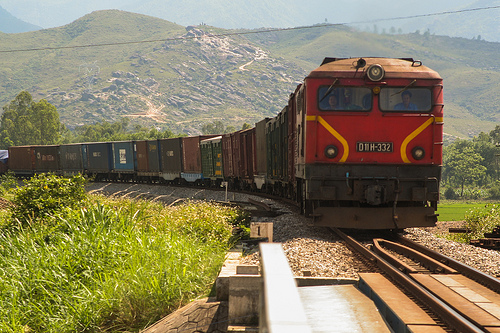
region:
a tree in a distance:
[34, 165, 83, 213]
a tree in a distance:
[1, 88, 63, 151]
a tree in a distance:
[34, 97, 65, 142]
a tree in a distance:
[73, 120, 103, 139]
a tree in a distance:
[108, 118, 130, 140]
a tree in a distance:
[141, 124, 171, 138]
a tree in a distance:
[439, 138, 483, 187]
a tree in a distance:
[470, 130, 497, 153]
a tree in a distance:
[389, 23, 398, 35]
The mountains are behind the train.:
[13, 4, 400, 96]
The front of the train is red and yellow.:
[285, 43, 446, 241]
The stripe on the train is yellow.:
[393, 114, 448, 166]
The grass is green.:
[8, 163, 195, 283]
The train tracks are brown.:
[342, 212, 485, 296]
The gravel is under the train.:
[271, 202, 388, 284]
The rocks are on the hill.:
[122, 0, 278, 132]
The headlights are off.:
[296, 132, 452, 174]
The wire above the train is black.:
[17, 12, 462, 73]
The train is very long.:
[0, 85, 339, 186]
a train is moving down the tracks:
[11, 54, 451, 266]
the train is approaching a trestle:
[122, 61, 498, 326]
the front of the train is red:
[300, 54, 445, 243]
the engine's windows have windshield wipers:
[307, 64, 442, 125]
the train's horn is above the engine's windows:
[358, 60, 390, 91]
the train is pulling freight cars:
[11, 55, 444, 234]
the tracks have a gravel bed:
[21, 172, 498, 310]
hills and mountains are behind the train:
[6, 4, 498, 180]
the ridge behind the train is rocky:
[31, 23, 393, 144]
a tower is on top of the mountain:
[313, 14, 336, 34]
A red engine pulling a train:
[282, 47, 442, 229]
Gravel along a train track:
[425, 227, 490, 271]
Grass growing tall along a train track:
[33, 222, 210, 303]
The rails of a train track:
[377, 239, 482, 330]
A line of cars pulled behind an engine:
[36, 103, 276, 183]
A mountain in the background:
[82, 5, 363, 99]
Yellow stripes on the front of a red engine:
[292, 104, 480, 184]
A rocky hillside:
[102, 34, 269, 121]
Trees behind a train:
[15, 92, 68, 139]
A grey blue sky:
[186, 3, 264, 18]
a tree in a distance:
[13, 87, 38, 143]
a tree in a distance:
[81, 117, 107, 150]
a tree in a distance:
[129, 129, 144, 139]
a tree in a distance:
[464, 144, 485, 183]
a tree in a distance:
[476, 139, 491, 166]